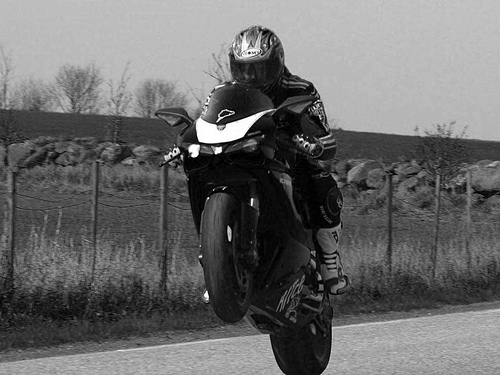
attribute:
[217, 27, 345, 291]
man — holding, jumping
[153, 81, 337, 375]
motorcycle — printed, up, black, white, striped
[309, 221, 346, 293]
boots — white, protective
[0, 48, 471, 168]
trees — bare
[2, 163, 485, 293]
posts — wooden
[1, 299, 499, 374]
road — country, here, edged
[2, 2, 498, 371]
photo — black, white, monochromatic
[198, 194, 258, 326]
tire — black, rubber, here, airborne, touching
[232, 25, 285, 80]
helmet — decorated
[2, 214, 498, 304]
grass — tall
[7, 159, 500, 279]
fence — here